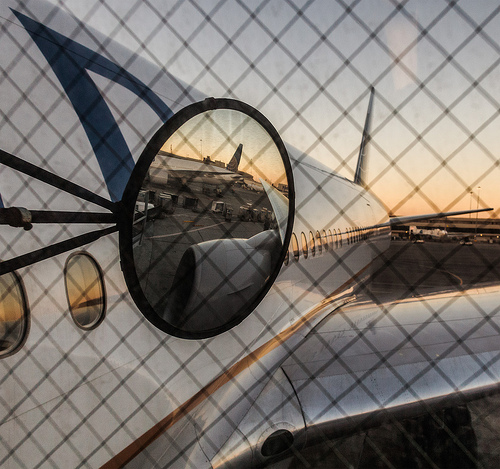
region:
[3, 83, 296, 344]
a side view mirror on the plane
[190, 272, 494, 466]
a wing on the plane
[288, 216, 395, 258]
the windows on the side of the plane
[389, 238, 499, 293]
part of the runway of the plane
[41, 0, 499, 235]
the sunny sky all around the plane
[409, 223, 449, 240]
a truck on the runway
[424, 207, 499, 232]
a building in the background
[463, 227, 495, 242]
a car in the background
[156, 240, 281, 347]
a reflection of the engine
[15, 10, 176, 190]
writing on the plane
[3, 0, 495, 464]
a plane parked on the runway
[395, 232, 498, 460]
the runway next to the plane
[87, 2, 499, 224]
the bright sky at sunset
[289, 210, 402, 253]
a long line of windows on the side of the plane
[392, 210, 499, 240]
a building in the background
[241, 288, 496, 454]
the wing of the plane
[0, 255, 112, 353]
two little windows on the plane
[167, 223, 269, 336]
the engine of the plane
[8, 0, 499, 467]
Airplane is white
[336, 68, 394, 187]
Vertical stabilizer of plane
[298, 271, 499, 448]
Right wing of plane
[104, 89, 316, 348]
Mirror of plane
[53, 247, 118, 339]
Window of plane is round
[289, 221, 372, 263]
Windows of plane on side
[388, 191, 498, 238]
Right stabilizer of plane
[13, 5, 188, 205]
Letter is paint on plane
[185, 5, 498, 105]
Sky is blue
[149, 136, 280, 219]
Plain reflected on mirror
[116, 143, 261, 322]
Reflection of plane in mirror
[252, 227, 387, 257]
Many windows in a line on the side of the plane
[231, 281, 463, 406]
Large white wing on plane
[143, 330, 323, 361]
Gold stripe on side of plane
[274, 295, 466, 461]
Gray chain link fence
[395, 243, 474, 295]
Lines on ground near plane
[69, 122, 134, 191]
Blue coloring on airplane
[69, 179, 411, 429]
Airplane on ground near airport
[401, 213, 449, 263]
Airplane in background on ground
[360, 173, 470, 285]
Airport in background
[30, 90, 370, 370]
round mirror in front of plane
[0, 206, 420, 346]
row of oval airplane windows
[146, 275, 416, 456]
wing connected to plane body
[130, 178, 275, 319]
reflection of engine and luggage carts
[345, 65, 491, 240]
metal jutting out of rear of plane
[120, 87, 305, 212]
reflection of airplanes on the ground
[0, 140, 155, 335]
supporting poles holding mirror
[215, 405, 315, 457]
circle on curve of wing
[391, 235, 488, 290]
dark surface of tarmac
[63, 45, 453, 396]
diamond pattern of wire fencing